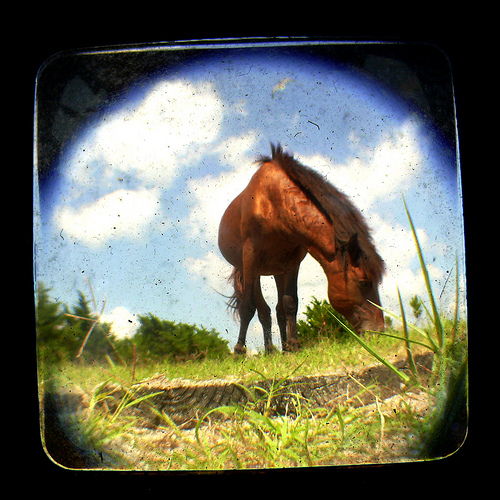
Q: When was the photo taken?
A: Daytime.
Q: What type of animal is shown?
A: Horse.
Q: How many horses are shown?
A: One.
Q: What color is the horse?
A: Brown.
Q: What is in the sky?
A: Clouds.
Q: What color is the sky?
A: Blue.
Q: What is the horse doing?
A: Eating.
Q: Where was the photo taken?
A: In a field.